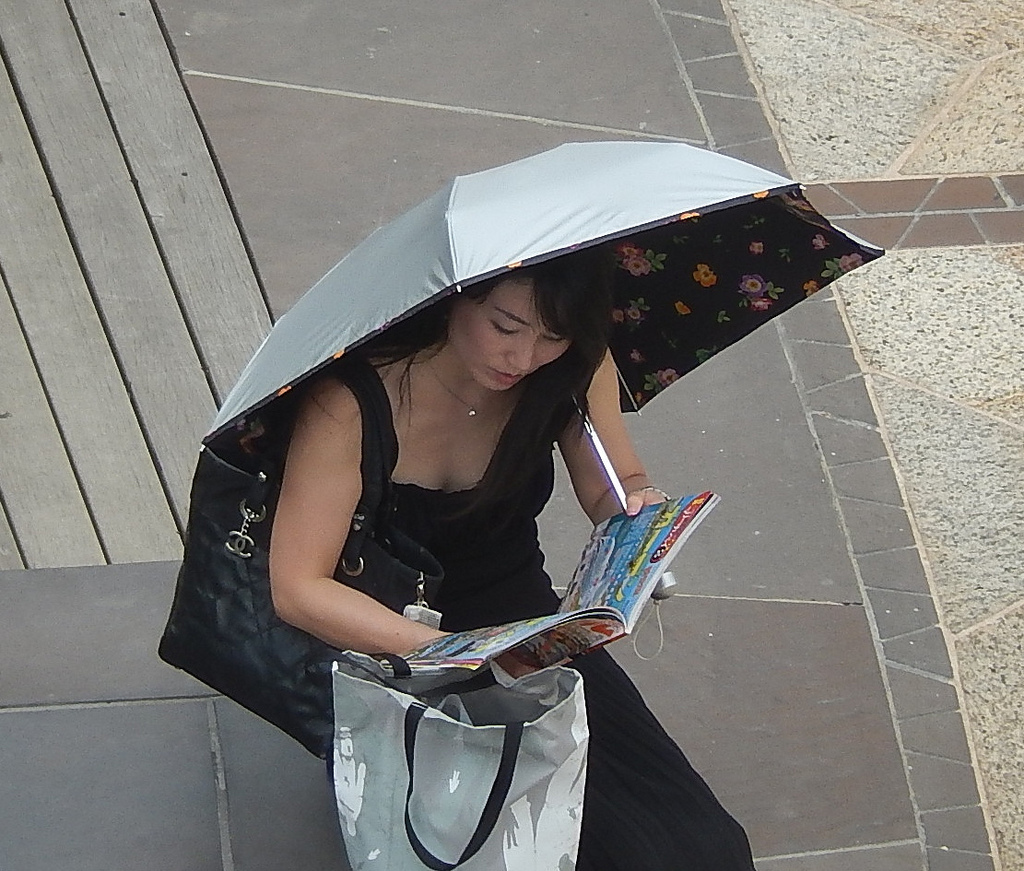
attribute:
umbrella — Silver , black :
[157, 72, 909, 500]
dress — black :
[274, 394, 815, 820]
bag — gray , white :
[347, 640, 670, 850]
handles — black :
[384, 685, 523, 850]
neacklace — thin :
[417, 370, 534, 433]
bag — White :
[280, 631, 698, 848]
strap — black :
[402, 668, 545, 856]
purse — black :
[274, 640, 758, 861]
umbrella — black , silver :
[175, 132, 901, 433]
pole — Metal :
[576, 404, 689, 603]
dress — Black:
[287, 420, 715, 803]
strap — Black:
[360, 698, 572, 846]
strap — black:
[341, 361, 413, 495]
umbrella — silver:
[194, 122, 899, 622]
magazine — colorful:
[395, 485, 724, 682]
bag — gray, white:
[321, 644, 590, 867]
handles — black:
[369, 655, 532, 865]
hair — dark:
[535, 251, 622, 466]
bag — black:
[153, 363, 456, 787]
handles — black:
[362, 642, 535, 867]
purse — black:
[140, 357, 449, 774]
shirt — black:
[351, 364, 566, 635]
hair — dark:
[520, 249, 620, 451]